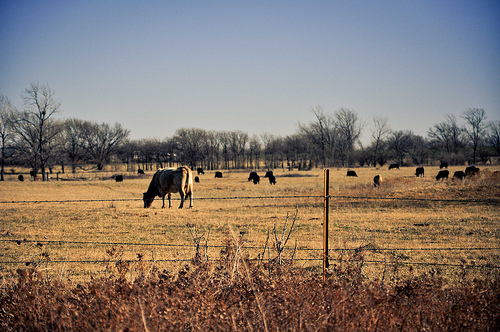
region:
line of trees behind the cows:
[209, 120, 346, 169]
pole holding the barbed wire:
[319, 160, 344, 283]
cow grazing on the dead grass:
[128, 160, 202, 214]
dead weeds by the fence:
[23, 260, 273, 330]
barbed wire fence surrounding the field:
[14, 177, 361, 289]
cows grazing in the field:
[337, 154, 462, 191]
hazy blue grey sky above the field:
[120, 23, 364, 85]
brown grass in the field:
[41, 209, 138, 236]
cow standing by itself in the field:
[136, 162, 201, 219]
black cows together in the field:
[239, 165, 283, 191]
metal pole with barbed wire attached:
[314, 162, 342, 287]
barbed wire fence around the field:
[11, 191, 113, 308]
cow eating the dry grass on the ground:
[133, 163, 205, 210]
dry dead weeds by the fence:
[41, 253, 233, 328]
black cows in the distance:
[241, 165, 278, 185]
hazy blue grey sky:
[99, 25, 295, 102]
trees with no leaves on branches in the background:
[2, 86, 98, 183]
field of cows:
[133, 148, 458, 253]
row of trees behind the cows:
[191, 125, 298, 170]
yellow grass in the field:
[359, 210, 454, 247]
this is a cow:
[140, 162, 197, 206]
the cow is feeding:
[139, 160, 197, 206]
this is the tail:
[183, 170, 190, 185]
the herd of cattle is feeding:
[368, 156, 484, 183]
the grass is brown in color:
[178, 271, 343, 330]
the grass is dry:
[155, 264, 341, 329]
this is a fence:
[303, 182, 359, 212]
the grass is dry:
[263, 193, 312, 222]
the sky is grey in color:
[158, 15, 315, 79]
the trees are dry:
[20, 93, 55, 154]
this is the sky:
[68, 7, 427, 82]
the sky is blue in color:
[135, 32, 258, 81]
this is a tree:
[298, 105, 347, 166]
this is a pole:
[318, 165, 341, 272]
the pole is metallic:
[318, 165, 342, 251]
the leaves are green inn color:
[30, 86, 65, 103]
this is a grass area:
[46, 205, 134, 234]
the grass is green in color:
[36, 197, 111, 231]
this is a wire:
[50, 192, 124, 207]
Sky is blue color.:
[92, 40, 344, 108]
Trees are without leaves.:
[22, 104, 496, 171]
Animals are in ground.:
[23, 138, 467, 267]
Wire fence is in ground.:
[23, 163, 474, 288]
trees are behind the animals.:
[26, 96, 473, 206]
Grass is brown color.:
[36, 183, 131, 248]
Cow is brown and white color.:
[135, 170, 210, 220]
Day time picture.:
[29, 50, 496, 328]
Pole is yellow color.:
[312, 157, 347, 264]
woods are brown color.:
[6, 110, 475, 170]